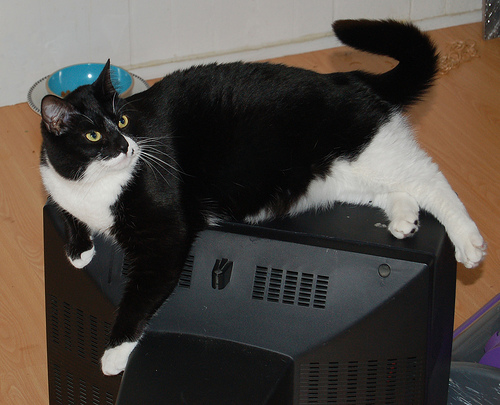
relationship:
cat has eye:
[31, 14, 491, 290] [81, 126, 107, 142]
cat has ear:
[31, 14, 491, 290] [93, 61, 137, 105]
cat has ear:
[31, 14, 491, 290] [37, 91, 81, 136]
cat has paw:
[31, 14, 491, 290] [55, 233, 112, 272]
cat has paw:
[31, 14, 491, 290] [373, 194, 427, 246]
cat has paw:
[31, 14, 491, 290] [93, 323, 141, 380]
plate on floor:
[24, 78, 157, 111] [0, 85, 495, 311]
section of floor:
[403, 15, 497, 121] [0, 85, 495, 311]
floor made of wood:
[0, 85, 495, 311] [436, 97, 498, 164]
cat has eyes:
[31, 14, 491, 290] [76, 111, 134, 141]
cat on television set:
[31, 14, 491, 290] [33, 242, 465, 397]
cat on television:
[31, 14, 491, 290] [33, 242, 465, 397]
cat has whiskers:
[31, 14, 491, 290] [131, 131, 188, 177]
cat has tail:
[31, 14, 491, 290] [325, 11, 443, 98]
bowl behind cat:
[46, 60, 139, 92] [31, 14, 491, 290]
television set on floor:
[33, 242, 465, 397] [0, 85, 495, 311]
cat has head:
[31, 14, 491, 290] [42, 81, 147, 170]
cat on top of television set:
[31, 14, 491, 290] [33, 242, 465, 397]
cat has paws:
[31, 14, 491, 290] [378, 199, 498, 269]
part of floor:
[436, 97, 498, 164] [0, 85, 495, 311]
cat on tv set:
[31, 14, 491, 290] [33, 242, 465, 397]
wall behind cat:
[134, 6, 277, 41] [31, 14, 491, 290]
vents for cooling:
[247, 259, 332, 311] [247, 265, 314, 301]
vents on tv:
[247, 259, 332, 311] [33, 242, 465, 397]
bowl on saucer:
[46, 60, 139, 92] [21, 71, 59, 111]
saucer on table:
[21, 71, 59, 111] [461, 55, 488, 204]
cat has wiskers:
[31, 14, 491, 290] [131, 131, 188, 177]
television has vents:
[33, 242, 465, 397] [247, 259, 332, 311]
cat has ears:
[31, 14, 491, 290] [34, 59, 120, 132]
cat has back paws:
[31, 14, 491, 290] [378, 199, 498, 269]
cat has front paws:
[31, 14, 491, 290] [57, 238, 150, 376]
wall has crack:
[134, 6, 277, 41] [114, 11, 144, 57]